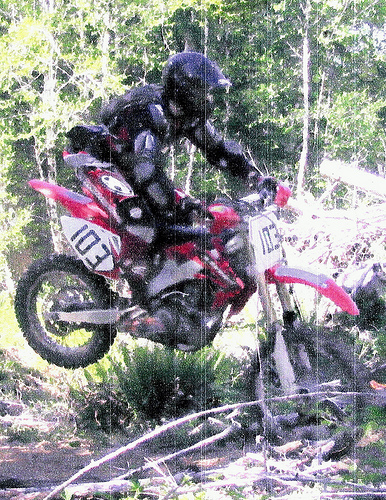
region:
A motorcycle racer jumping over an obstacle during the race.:
[10, 15, 375, 467]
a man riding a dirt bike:
[25, 63, 363, 393]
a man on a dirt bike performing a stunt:
[0, 40, 372, 410]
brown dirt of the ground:
[14, 433, 88, 490]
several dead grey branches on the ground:
[86, 379, 340, 498]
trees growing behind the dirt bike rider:
[250, 2, 377, 155]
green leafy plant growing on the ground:
[79, 344, 231, 441]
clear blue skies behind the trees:
[343, 12, 385, 71]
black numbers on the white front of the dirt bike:
[250, 217, 285, 263]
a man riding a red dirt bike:
[32, 58, 352, 434]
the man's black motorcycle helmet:
[155, 42, 233, 118]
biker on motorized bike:
[12, 41, 358, 484]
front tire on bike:
[246, 336, 373, 454]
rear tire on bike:
[4, 254, 114, 359]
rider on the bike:
[101, 46, 275, 223]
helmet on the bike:
[162, 45, 235, 108]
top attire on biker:
[107, 78, 248, 182]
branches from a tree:
[69, 389, 376, 455]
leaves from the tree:
[1, 0, 382, 60]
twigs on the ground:
[151, 449, 379, 496]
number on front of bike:
[242, 208, 287, 265]